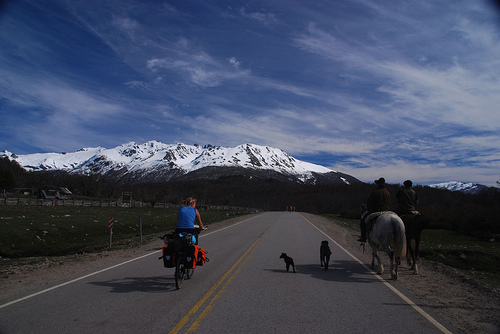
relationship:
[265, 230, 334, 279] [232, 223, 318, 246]
dogs on road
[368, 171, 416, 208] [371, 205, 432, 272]
people riding horses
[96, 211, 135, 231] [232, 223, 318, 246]
grass along road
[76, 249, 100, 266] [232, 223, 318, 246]
dirt along road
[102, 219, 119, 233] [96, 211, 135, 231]
sign in grass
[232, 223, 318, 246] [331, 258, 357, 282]
road has shadows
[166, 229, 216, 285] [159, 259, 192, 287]
bike has wheel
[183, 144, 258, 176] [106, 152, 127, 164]
mountains have snow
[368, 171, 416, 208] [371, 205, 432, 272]
people on horses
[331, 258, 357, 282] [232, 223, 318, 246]
shadows on road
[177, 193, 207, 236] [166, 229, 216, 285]
woman riding bike